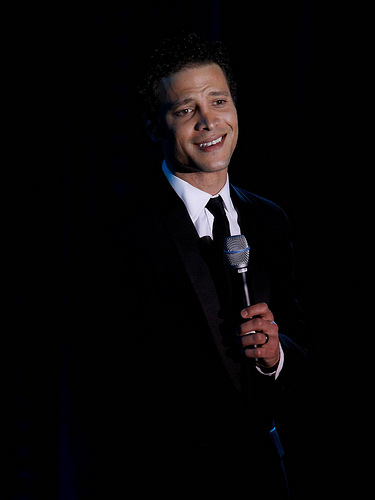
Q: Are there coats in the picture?
A: Yes, there is a coat.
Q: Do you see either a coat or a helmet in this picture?
A: Yes, there is a coat.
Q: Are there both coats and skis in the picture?
A: No, there is a coat but no skis.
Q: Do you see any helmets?
A: No, there are no helmets.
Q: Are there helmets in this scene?
A: No, there are no helmets.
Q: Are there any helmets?
A: No, there are no helmets.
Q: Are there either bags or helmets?
A: No, there are no helmets or bags.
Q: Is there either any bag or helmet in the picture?
A: No, there are no helmets or bags.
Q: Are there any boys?
A: No, there are no boys.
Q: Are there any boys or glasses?
A: No, there are no boys or glasses.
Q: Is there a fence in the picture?
A: No, there are no fences.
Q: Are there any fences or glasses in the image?
A: No, there are no fences or glasses.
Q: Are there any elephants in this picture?
A: No, there are no elephants.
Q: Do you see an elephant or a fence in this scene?
A: No, there are no elephants or fences.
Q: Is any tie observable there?
A: Yes, there is a tie.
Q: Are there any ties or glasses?
A: Yes, there is a tie.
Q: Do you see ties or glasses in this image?
A: Yes, there is a tie.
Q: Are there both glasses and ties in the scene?
A: No, there is a tie but no glasses.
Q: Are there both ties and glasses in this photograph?
A: No, there is a tie but no glasses.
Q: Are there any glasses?
A: No, there are no glasses.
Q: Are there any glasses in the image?
A: No, there are no glasses.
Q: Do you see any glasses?
A: No, there are no glasses.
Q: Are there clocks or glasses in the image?
A: No, there are no glasses or clocks.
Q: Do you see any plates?
A: No, there are no plates.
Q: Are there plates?
A: No, there are no plates.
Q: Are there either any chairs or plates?
A: No, there are no plates or chairs.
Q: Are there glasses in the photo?
A: No, there are no glasses.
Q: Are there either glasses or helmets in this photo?
A: No, there are no glasses or helmets.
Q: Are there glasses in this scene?
A: No, there are no glasses.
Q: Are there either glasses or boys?
A: No, there are no glasses or boys.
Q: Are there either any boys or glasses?
A: No, there are no glasses or boys.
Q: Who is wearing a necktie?
A: The man is wearing a necktie.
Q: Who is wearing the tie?
A: The man is wearing a necktie.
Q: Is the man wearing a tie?
A: Yes, the man is wearing a tie.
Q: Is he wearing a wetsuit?
A: No, the man is wearing a tie.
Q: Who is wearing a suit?
A: The man is wearing a suit.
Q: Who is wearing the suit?
A: The man is wearing a suit.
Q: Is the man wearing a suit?
A: Yes, the man is wearing a suit.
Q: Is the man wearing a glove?
A: No, the man is wearing a suit.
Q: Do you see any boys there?
A: No, there are no boys.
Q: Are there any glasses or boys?
A: No, there are no boys or glasses.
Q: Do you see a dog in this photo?
A: No, there are no dogs.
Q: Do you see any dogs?
A: No, there are no dogs.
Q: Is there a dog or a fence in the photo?
A: No, there are no dogs or fences.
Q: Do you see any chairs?
A: No, there are no chairs.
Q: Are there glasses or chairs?
A: No, there are no chairs or glasses.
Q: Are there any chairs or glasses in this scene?
A: No, there are no chairs or glasses.